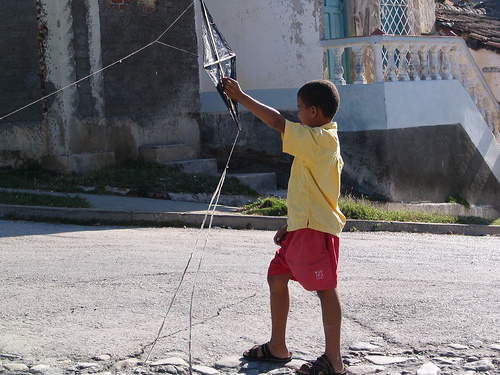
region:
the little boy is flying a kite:
[203, 1, 370, 373]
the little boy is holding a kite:
[189, 4, 247, 122]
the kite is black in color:
[196, 3, 242, 110]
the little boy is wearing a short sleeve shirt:
[281, 118, 348, 238]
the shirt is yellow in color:
[274, 119, 346, 239]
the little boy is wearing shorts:
[264, 232, 341, 291]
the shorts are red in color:
[266, 221, 343, 291]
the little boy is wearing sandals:
[241, 339, 344, 374]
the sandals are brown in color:
[245, 340, 345, 373]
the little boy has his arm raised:
[220, 70, 299, 150]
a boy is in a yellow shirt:
[224, 85, 454, 251]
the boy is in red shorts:
[212, 203, 460, 318]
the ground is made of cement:
[121, 288, 269, 370]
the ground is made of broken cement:
[357, 345, 421, 367]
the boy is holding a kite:
[147, 3, 363, 161]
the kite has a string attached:
[213, 108, 267, 358]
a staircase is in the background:
[311, 13, 488, 98]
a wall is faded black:
[29, 8, 235, 189]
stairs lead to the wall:
[114, 110, 342, 270]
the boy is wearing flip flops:
[227, 339, 379, 367]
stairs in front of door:
[335, 38, 495, 197]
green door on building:
[323, 1, 348, 75]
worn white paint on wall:
[200, 1, 323, 89]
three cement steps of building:
[153, 139, 272, 191]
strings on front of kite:
[1, 0, 238, 135]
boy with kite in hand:
[200, 4, 348, 371]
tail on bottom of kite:
[151, 126, 242, 371]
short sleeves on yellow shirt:
[281, 121, 347, 235]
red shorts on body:
[268, 227, 338, 290]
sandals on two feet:
[243, 342, 347, 374]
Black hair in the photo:
[299, 82, 345, 105]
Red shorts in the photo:
[279, 227, 341, 284]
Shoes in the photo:
[241, 337, 333, 372]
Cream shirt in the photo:
[289, 117, 338, 230]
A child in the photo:
[227, 59, 385, 366]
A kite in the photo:
[149, 14, 254, 129]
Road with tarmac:
[55, 284, 159, 342]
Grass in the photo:
[237, 183, 400, 225]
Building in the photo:
[146, 53, 248, 150]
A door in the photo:
[327, 10, 352, 75]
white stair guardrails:
[324, 31, 476, 74]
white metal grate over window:
[376, 0, 410, 35]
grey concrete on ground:
[35, 238, 137, 336]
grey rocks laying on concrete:
[363, 330, 497, 373]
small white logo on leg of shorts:
[306, 265, 332, 278]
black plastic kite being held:
[185, 5, 262, 122]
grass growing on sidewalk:
[350, 197, 479, 245]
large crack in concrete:
[207, 282, 260, 322]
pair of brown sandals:
[230, 333, 370, 373]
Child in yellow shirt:
[253, 48, 386, 373]